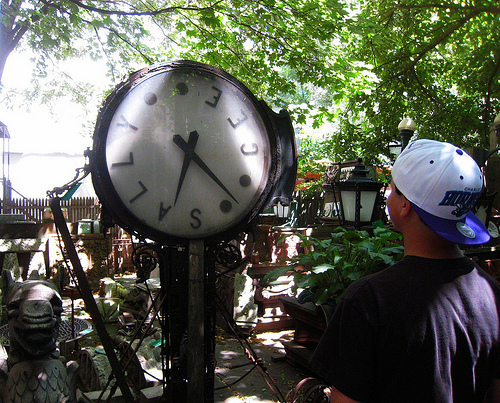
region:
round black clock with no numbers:
[91, 42, 321, 270]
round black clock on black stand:
[91, 47, 303, 381]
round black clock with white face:
[89, 36, 308, 262]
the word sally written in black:
[116, 107, 208, 235]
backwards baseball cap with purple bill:
[388, 130, 490, 255]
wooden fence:
[0, 194, 105, 224]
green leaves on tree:
[228, 12, 496, 119]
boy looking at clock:
[338, 111, 495, 396]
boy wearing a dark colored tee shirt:
[296, 126, 495, 371]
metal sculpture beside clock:
[7, 262, 88, 401]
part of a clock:
[176, 94, 204, 114]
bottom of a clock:
[161, 225, 178, 246]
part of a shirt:
[418, 298, 435, 310]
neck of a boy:
[413, 223, 420, 241]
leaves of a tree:
[365, 90, 384, 119]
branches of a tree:
[349, 79, 369, 101]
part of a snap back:
[430, 167, 455, 174]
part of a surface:
[263, 334, 268, 343]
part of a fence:
[78, 200, 88, 211]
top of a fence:
[33, 197, 54, 201]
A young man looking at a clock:
[298, 128, 499, 401]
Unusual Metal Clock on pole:
[69, 39, 307, 401]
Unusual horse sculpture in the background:
[5, 253, 85, 401]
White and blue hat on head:
[392, 124, 496, 254]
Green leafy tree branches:
[223, 3, 498, 109]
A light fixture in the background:
[321, 152, 388, 240]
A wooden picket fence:
[0, 192, 102, 222]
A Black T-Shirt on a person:
[312, 250, 499, 400]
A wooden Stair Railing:
[0, 184, 51, 229]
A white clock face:
[108, 63, 275, 240]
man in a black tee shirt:
[304, 134, 498, 401]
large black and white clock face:
[82, 46, 299, 256]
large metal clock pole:
[128, 234, 250, 401]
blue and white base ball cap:
[377, 131, 499, 256]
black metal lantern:
[322, 156, 388, 242]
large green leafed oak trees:
[1, 0, 498, 154]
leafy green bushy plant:
[256, 220, 399, 308]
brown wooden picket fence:
[5, 194, 122, 222]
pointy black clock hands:
[159, 128, 241, 213]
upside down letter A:
[148, 197, 178, 227]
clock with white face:
[87, 43, 300, 247]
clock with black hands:
[82, 61, 299, 253]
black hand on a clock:
[168, 131, 246, 204]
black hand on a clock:
[162, 126, 201, 211]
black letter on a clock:
[127, 176, 149, 211]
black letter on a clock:
[106, 148, 140, 171]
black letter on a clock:
[113, 108, 143, 134]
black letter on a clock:
[200, 80, 224, 110]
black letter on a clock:
[225, 106, 251, 129]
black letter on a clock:
[236, 140, 262, 157]